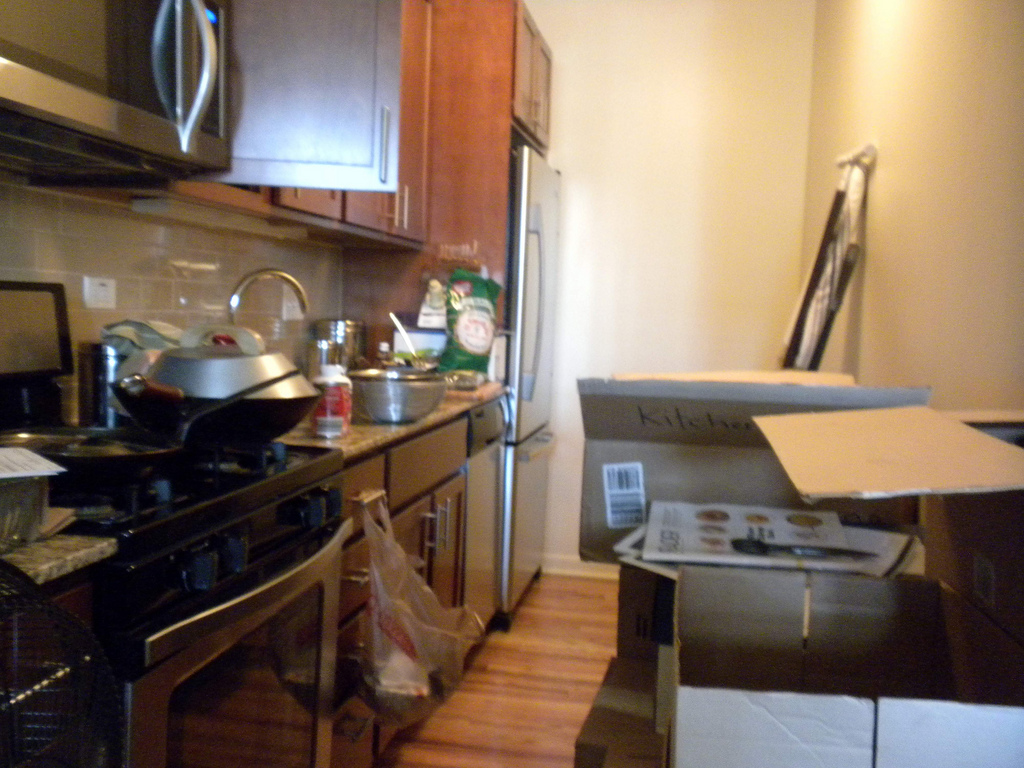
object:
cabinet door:
[187, 0, 400, 196]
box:
[578, 370, 932, 566]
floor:
[377, 557, 670, 767]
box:
[611, 501, 939, 699]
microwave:
[0, 0, 233, 178]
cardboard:
[896, 423, 957, 470]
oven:
[0, 425, 345, 768]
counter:
[273, 366, 509, 461]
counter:
[0, 534, 120, 593]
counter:
[573, 652, 671, 768]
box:
[663, 406, 1024, 768]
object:
[781, 144, 872, 372]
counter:
[655, 638, 679, 734]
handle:
[425, 497, 452, 557]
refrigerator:
[466, 144, 562, 633]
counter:
[575, 343, 1022, 580]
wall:
[800, 0, 1021, 412]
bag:
[359, 490, 487, 727]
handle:
[139, 518, 358, 669]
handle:
[173, 0, 249, 157]